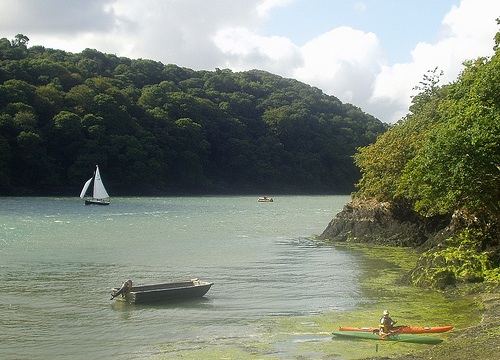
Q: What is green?
A: Trees.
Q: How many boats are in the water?
A: Four.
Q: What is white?
A: A sailboat.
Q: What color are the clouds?
A: White.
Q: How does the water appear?
A: Calm.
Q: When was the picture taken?
A: Daytime.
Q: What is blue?
A: Sky.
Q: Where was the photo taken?
A: On a calm river.